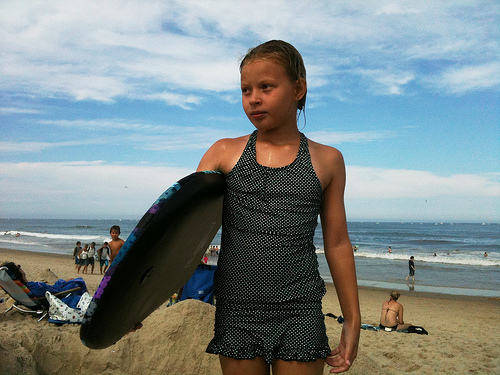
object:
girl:
[130, 40, 363, 375]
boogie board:
[75, 170, 226, 348]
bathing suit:
[205, 130, 335, 364]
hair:
[240, 40, 308, 111]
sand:
[0, 248, 499, 375]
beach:
[0, 247, 499, 375]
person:
[406, 256, 416, 280]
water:
[1, 218, 500, 291]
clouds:
[1, 0, 500, 117]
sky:
[1, 0, 500, 224]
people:
[377, 288, 410, 332]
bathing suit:
[378, 307, 400, 332]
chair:
[0, 265, 80, 321]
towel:
[360, 321, 428, 334]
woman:
[1, 260, 87, 299]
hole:
[0, 301, 226, 375]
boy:
[107, 226, 127, 262]